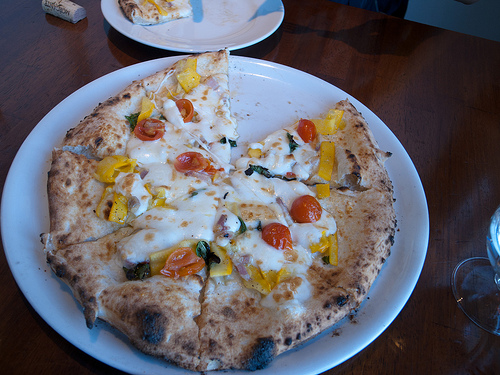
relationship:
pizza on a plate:
[38, 47, 400, 374] [18, 63, 450, 370]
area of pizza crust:
[236, 339, 278, 366] [41, 49, 396, 371]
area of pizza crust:
[138, 294, 172, 335] [41, 49, 396, 371]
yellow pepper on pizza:
[174, 56, 199, 91] [38, 47, 400, 374]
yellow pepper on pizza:
[133, 95, 155, 122] [38, 47, 400, 374]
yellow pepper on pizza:
[94, 155, 134, 184] [38, 47, 400, 374]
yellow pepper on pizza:
[96, 187, 128, 221] [38, 47, 400, 374]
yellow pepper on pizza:
[144, 184, 174, 209] [38, 47, 400, 374]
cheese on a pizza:
[162, 200, 212, 240] [38, 47, 400, 374]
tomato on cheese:
[132, 113, 169, 142] [120, 110, 217, 170]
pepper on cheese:
[302, 134, 347, 208] [236, 119, 314, 179]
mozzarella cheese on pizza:
[145, 212, 200, 252] [86, 217, 210, 341]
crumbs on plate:
[231, 64, 307, 147] [8, 66, 495, 370]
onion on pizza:
[276, 191, 295, 228] [38, 47, 400, 374]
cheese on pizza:
[238, 127, 321, 178] [38, 47, 400, 374]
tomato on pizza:
[292, 197, 317, 224] [38, 47, 400, 374]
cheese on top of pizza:
[169, 188, 223, 247] [8, 44, 447, 366]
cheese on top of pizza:
[102, 151, 299, 251] [38, 47, 400, 374]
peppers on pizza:
[80, 148, 143, 183] [46, 73, 410, 357]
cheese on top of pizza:
[90, 71, 354, 300] [38, 47, 400, 374]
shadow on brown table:
[292, 8, 434, 59] [0, 9, 500, 375]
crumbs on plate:
[241, 86, 304, 123] [271, 70, 316, 98]